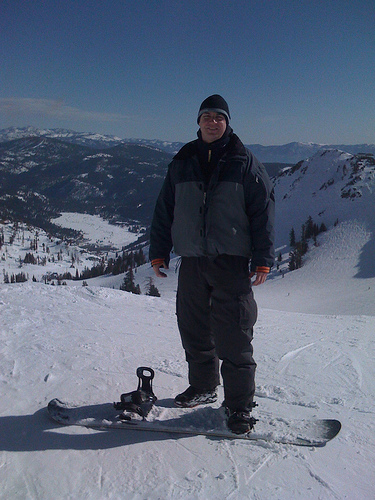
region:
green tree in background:
[145, 280, 160, 295]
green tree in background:
[118, 265, 135, 294]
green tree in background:
[129, 281, 144, 296]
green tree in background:
[275, 249, 283, 261]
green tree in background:
[286, 253, 297, 270]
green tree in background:
[292, 247, 300, 265]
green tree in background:
[288, 225, 296, 246]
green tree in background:
[3, 271, 12, 282]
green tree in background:
[9, 272, 18, 281]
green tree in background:
[54, 278, 64, 285]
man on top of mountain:
[170, 88, 287, 392]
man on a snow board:
[160, 88, 281, 449]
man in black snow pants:
[175, 94, 283, 412]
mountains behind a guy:
[13, 112, 196, 286]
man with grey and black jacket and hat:
[178, 97, 279, 320]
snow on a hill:
[61, 292, 304, 421]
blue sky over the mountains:
[81, 46, 363, 97]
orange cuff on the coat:
[249, 256, 289, 288]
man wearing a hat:
[194, 97, 248, 143]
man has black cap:
[195, 93, 234, 123]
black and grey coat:
[157, 153, 268, 254]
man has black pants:
[168, 256, 280, 403]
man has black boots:
[172, 379, 243, 433]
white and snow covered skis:
[76, 375, 364, 464]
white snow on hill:
[283, 307, 366, 406]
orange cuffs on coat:
[254, 254, 274, 281]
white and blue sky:
[37, 22, 151, 122]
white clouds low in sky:
[20, 92, 93, 125]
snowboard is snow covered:
[270, 417, 297, 445]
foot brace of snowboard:
[123, 384, 135, 407]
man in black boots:
[233, 418, 254, 434]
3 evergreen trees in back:
[119, 275, 152, 289]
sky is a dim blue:
[286, 103, 326, 135]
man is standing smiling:
[193, 125, 243, 145]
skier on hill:
[114, 75, 291, 472]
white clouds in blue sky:
[309, 46, 370, 71]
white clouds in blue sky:
[277, 83, 325, 119]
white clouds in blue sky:
[199, 0, 234, 27]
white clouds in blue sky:
[137, 40, 173, 67]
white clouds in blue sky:
[87, 51, 120, 96]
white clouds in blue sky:
[39, 69, 80, 112]